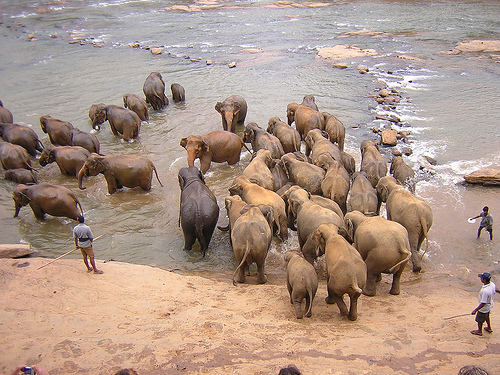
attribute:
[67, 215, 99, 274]
man — standing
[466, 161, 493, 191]
rock — brown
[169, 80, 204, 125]
small elephant — one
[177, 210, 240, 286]
black elephant — one